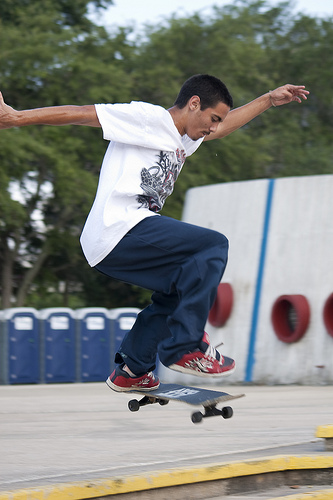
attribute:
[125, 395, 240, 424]
wheels — some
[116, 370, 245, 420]
skateboard — one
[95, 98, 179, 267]
shirt — white, beautiful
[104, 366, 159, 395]
shoe — man's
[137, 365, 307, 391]
shoe — red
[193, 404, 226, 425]
wheel — grey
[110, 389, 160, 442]
wheel — grey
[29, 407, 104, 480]
ground — grey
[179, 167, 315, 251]
pole — blue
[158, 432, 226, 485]
line — yellow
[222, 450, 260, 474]
line — yellow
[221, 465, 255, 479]
line — yellow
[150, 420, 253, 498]
line — yellow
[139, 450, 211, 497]
line — yellow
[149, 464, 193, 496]
line — yellow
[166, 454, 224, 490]
line — yellow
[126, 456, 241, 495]
line — yellow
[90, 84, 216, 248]
man — skating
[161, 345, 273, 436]
shoes — red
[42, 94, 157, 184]
shirt — white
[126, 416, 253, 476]
line — yellow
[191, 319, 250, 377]
laces — white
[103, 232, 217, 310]
pants — blue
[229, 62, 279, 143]
arm — extended